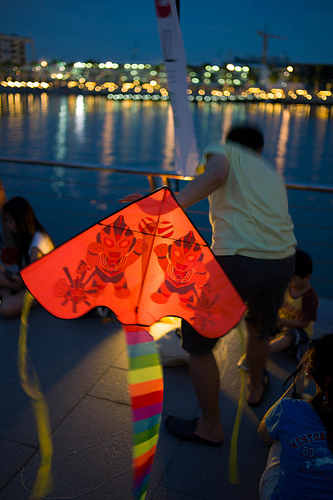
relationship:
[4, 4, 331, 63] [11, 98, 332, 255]
sky above water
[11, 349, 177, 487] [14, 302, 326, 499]
lines on top of ground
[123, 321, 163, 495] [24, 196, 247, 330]
tail of kite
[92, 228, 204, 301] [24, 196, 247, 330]
figures on front of kite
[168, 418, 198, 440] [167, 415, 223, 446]
shoe on foot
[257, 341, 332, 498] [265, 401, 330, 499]
person wearing shirt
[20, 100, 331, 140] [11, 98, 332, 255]
reflection on top of water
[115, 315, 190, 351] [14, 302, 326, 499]
light hitting ground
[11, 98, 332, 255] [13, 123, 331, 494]
water next to people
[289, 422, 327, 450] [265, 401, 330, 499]
word on back of shirt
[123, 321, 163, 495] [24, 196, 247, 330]
tail in center of kite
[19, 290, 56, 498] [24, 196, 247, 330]
tail of kite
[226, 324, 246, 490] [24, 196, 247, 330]
tail of kite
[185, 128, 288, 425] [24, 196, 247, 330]
person holding kite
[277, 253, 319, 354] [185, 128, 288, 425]
boy by person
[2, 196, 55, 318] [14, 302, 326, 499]
girl on top of ground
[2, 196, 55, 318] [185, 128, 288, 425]
girl next to person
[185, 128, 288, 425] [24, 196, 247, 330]
person with kite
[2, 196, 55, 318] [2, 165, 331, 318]
girl by fence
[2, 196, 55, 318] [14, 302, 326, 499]
girl sitting on ground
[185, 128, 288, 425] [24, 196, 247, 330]
person holds kite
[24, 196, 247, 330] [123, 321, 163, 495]
kite has tail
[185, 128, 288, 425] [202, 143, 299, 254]
person has shirt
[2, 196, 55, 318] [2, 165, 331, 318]
girl near fence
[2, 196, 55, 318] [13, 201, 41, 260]
girl has hair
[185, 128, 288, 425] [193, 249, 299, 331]
person has shorts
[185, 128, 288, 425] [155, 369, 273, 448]
person wearing sandals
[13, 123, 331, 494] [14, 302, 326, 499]
people on ground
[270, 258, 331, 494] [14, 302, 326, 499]
kids on top of ground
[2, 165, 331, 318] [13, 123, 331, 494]
fence in front of people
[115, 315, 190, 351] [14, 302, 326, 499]
light shines on ground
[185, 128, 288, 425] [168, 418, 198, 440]
person has shoe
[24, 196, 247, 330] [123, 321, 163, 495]
kite with tail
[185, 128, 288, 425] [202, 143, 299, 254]
person with shirt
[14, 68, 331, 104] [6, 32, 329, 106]
lights on top of shore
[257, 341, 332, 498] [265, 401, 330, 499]
person with shirt